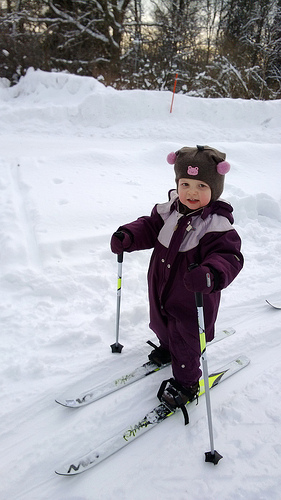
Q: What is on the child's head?
A: A hat.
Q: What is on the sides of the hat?
A: Fluffy balls.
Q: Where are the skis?
A: Under the boy.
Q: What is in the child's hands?
A: Ski poles.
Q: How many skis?
A: Two.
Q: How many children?
A: One.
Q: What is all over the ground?
A: Snow.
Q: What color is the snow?
A: White.